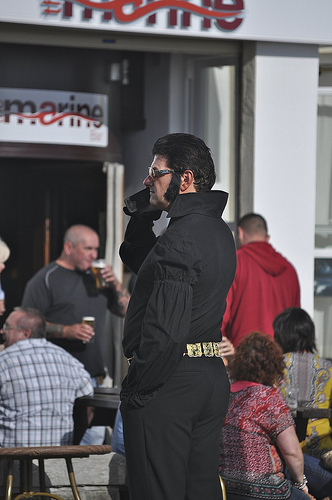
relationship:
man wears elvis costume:
[110, 126, 242, 497] [110, 130, 235, 499]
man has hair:
[110, 126, 242, 497] [148, 130, 217, 203]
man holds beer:
[20, 219, 134, 447] [86, 257, 113, 294]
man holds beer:
[20, 219, 134, 447] [79, 315, 97, 344]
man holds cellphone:
[110, 126, 242, 497] [121, 180, 158, 218]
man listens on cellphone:
[110, 126, 242, 497] [121, 180, 158, 218]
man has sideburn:
[110, 126, 242, 497] [162, 167, 185, 205]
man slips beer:
[20, 219, 134, 447] [86, 257, 113, 294]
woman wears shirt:
[221, 331, 316, 499] [219, 380, 297, 498]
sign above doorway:
[34, 0, 247, 38] [1, 21, 252, 499]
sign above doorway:
[3, 87, 112, 151] [0, 155, 116, 500]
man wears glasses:
[110, 126, 242, 497] [145, 160, 179, 181]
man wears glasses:
[0, 299, 103, 455] [1, 319, 28, 333]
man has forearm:
[20, 219, 134, 447] [104, 279, 129, 320]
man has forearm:
[20, 219, 134, 447] [42, 318, 68, 340]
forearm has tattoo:
[104, 279, 129, 320] [114, 285, 122, 297]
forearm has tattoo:
[104, 279, 129, 320] [113, 301, 126, 312]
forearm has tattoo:
[104, 279, 129, 320] [123, 289, 133, 303]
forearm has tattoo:
[104, 279, 129, 320] [111, 289, 123, 300]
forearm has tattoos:
[42, 318, 68, 340] [43, 322, 68, 338]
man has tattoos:
[20, 219, 134, 447] [43, 276, 133, 345]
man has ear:
[110, 126, 242, 497] [179, 165, 195, 192]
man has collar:
[110, 126, 242, 497] [161, 187, 231, 227]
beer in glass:
[86, 257, 113, 294] [85, 253, 111, 294]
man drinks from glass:
[20, 219, 134, 447] [85, 253, 111, 294]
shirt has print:
[219, 380, 297, 498] [224, 386, 292, 494]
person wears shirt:
[269, 306, 331, 466] [270, 350, 331, 459]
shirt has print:
[270, 350, 331, 459] [278, 350, 331, 451]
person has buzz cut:
[221, 209, 303, 397] [234, 213, 272, 243]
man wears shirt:
[0, 299, 103, 455] [1, 337, 94, 449]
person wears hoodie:
[221, 209, 303, 397] [222, 242, 299, 351]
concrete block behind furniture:
[0, 450, 128, 488] [0, 438, 116, 500]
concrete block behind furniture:
[2, 484, 123, 499] [0, 438, 116, 500]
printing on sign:
[42, 1, 243, 33] [34, 0, 247, 38]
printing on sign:
[0, 94, 105, 130] [3, 87, 112, 151]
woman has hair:
[221, 331, 316, 499] [223, 329, 285, 390]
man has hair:
[0, 299, 103, 455] [12, 304, 48, 342]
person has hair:
[269, 306, 331, 466] [269, 304, 321, 358]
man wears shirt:
[110, 126, 242, 497] [112, 187, 239, 408]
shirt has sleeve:
[112, 187, 239, 408] [113, 221, 198, 412]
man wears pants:
[110, 126, 242, 497] [120, 353, 236, 500]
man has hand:
[20, 219, 134, 447] [99, 265, 117, 286]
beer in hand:
[86, 257, 113, 294] [99, 265, 117, 286]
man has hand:
[20, 219, 134, 447] [66, 322, 97, 340]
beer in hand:
[79, 315, 97, 344] [66, 322, 97, 340]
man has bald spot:
[20, 219, 134, 447] [65, 223, 98, 244]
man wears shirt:
[20, 219, 134, 447] [18, 257, 111, 377]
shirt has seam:
[18, 257, 111, 377] [41, 265, 59, 289]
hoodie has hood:
[222, 242, 299, 351] [238, 240, 290, 281]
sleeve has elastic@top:
[113, 221, 198, 412] [151, 277, 192, 289]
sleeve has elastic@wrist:
[113, 221, 198, 412] [120, 378, 150, 401]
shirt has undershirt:
[219, 380, 297, 498] [227, 377, 261, 394]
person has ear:
[221, 209, 303, 397] [236, 224, 244, 243]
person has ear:
[221, 209, 303, 397] [264, 232, 271, 243]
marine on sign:
[6, 95, 105, 130] [3, 87, 112, 151]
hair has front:
[148, 130, 217, 203] [151, 132, 187, 158]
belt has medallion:
[126, 339, 223, 376] [186, 340, 204, 358]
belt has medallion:
[126, 339, 223, 376] [201, 340, 213, 359]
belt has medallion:
[126, 339, 223, 376] [212, 339, 221, 359]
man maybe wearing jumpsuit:
[110, 126, 242, 497] [110, 186, 239, 500]